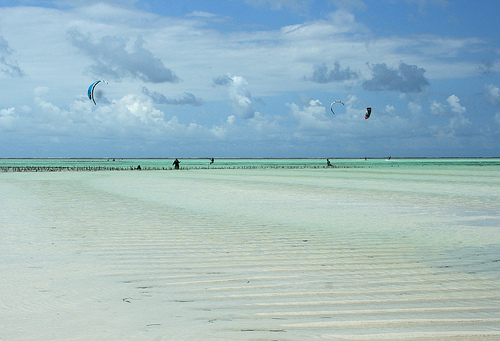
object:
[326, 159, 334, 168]
people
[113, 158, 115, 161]
people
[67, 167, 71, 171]
rocks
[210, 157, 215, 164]
person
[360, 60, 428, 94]
clouds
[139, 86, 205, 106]
clouds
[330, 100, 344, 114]
kite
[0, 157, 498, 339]
water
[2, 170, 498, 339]
sand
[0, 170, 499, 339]
beach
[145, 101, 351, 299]
wind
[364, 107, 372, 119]
kite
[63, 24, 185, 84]
clouds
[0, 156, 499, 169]
ocean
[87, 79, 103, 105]
kite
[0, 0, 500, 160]
sky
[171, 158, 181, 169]
people